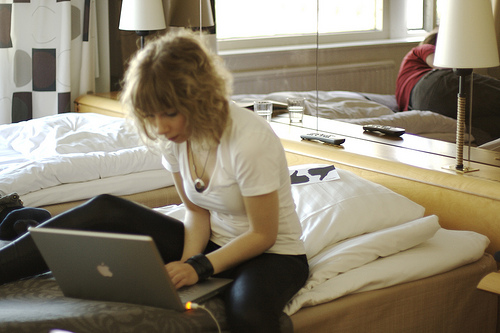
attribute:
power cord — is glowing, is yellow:
[185, 297, 221, 330]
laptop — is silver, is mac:
[23, 207, 261, 314]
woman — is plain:
[110, 24, 370, 302]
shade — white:
[430, 2, 499, 76]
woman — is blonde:
[97, 41, 402, 319]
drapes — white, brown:
[2, 0, 96, 132]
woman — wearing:
[86, 19, 389, 331]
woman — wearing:
[93, 33, 374, 323]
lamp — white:
[425, 5, 499, 175]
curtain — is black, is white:
[0, 4, 117, 124]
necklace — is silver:
[187, 138, 218, 194]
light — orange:
[183, 300, 194, 310]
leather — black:
[187, 253, 214, 281]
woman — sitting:
[0, 23, 317, 322]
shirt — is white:
[132, 102, 313, 257]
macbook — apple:
[27, 225, 234, 312]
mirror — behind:
[103, 2, 499, 167]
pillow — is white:
[288, 170, 438, 248]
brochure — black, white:
[288, 164, 340, 185]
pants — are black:
[228, 258, 306, 332]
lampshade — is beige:
[433, 1, 484, 77]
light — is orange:
[184, 301, 192, 310]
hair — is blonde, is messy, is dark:
[120, 32, 227, 132]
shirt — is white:
[223, 108, 290, 204]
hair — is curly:
[129, 30, 229, 137]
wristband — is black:
[185, 252, 215, 278]